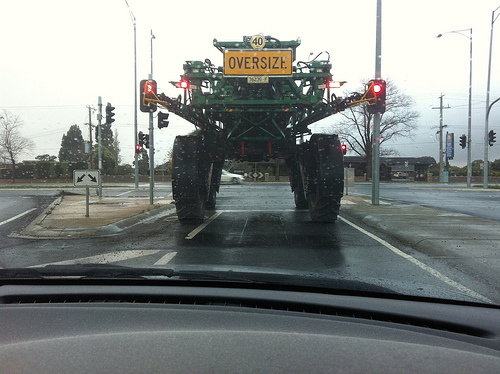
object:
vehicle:
[138, 32, 379, 226]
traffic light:
[367, 79, 386, 115]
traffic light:
[140, 79, 157, 113]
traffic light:
[488, 129, 496, 146]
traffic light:
[459, 134, 467, 150]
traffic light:
[157, 111, 169, 130]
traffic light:
[106, 102, 116, 125]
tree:
[0, 109, 34, 184]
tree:
[57, 124, 84, 163]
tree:
[132, 147, 149, 176]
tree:
[337, 79, 420, 182]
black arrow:
[87, 173, 97, 183]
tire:
[304, 133, 345, 223]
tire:
[289, 142, 309, 209]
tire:
[206, 158, 218, 209]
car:
[140, 32, 378, 224]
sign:
[344, 168, 356, 188]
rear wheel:
[306, 132, 344, 223]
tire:
[171, 135, 208, 219]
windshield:
[0, 0, 500, 311]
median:
[17, 194, 176, 239]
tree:
[87, 121, 117, 173]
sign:
[445, 132, 454, 159]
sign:
[224, 50, 293, 76]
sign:
[73, 169, 102, 187]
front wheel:
[205, 157, 224, 210]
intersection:
[1, 181, 494, 213]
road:
[0, 182, 497, 307]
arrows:
[76, 173, 86, 182]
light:
[436, 27, 475, 189]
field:
[0, 160, 138, 185]